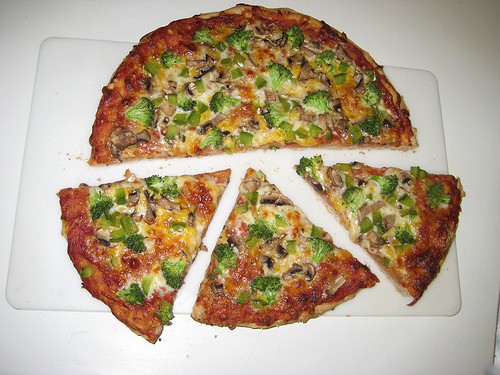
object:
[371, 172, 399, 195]
broccoli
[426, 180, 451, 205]
broccoli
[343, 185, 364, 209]
broccoli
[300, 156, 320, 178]
broccoli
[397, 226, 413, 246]
broccoli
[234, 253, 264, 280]
pizza sauce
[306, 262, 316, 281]
mushroom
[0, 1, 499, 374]
table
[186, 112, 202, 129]
bell pepper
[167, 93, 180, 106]
bell pepper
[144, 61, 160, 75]
bell pepper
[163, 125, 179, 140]
bell pepper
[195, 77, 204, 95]
bell pepper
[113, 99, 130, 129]
sauce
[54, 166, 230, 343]
pizza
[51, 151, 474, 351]
slices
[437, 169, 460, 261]
crust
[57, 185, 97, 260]
crunchy pizza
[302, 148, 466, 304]
pizza slice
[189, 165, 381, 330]
pizza slice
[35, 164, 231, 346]
pizza slice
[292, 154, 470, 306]
pizza slice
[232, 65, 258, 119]
cheese bubbles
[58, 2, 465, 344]
lunch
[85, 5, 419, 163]
half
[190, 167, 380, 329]
slice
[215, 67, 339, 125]
broccoli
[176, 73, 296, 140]
mushrooms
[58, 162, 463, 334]
half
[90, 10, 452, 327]
pizza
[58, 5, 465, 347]
pizza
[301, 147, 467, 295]
slice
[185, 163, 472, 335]
two slices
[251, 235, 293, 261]
mushroom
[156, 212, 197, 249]
cheese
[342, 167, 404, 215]
broccoli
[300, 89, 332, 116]
vegetable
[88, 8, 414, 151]
pizza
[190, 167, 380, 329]
pizza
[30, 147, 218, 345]
slice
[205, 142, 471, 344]
slices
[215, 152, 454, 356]
pizza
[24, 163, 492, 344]
slices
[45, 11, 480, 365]
picture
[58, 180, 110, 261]
crunchy part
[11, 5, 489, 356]
pieces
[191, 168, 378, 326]
crust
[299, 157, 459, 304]
pizza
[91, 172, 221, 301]
cheese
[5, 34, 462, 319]
cutting board